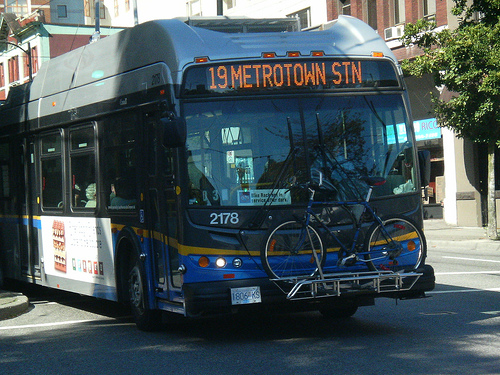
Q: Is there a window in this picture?
A: Yes, there is a window.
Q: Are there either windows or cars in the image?
A: Yes, there is a window.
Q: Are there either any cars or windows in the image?
A: Yes, there is a window.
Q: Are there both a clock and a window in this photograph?
A: No, there is a window but no clocks.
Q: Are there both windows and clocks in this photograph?
A: No, there is a window but no clocks.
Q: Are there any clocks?
A: No, there are no clocks.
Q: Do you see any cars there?
A: No, there are no cars.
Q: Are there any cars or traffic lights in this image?
A: No, there are no cars or traffic lights.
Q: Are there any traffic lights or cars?
A: No, there are no cars or traffic lights.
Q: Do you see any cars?
A: No, there are no cars.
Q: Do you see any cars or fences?
A: No, there are no cars or fences.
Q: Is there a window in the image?
A: Yes, there is a window.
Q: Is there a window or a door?
A: Yes, there is a window.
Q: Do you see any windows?
A: Yes, there is a window.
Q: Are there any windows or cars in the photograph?
A: Yes, there is a window.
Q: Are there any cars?
A: No, there are no cars.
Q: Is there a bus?
A: Yes, there is a bus.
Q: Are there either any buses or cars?
A: Yes, there is a bus.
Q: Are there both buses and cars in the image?
A: No, there is a bus but no cars.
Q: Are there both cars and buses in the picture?
A: No, there is a bus but no cars.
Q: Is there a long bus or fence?
A: Yes, there is a long bus.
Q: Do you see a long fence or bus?
A: Yes, there is a long bus.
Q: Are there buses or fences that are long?
A: Yes, the bus is long.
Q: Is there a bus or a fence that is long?
A: Yes, the bus is long.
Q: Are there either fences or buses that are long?
A: Yes, the bus is long.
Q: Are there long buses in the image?
A: Yes, there is a long bus.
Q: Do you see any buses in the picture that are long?
A: Yes, there is a bus that is long.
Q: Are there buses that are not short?
A: Yes, there is a long bus.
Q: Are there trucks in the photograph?
A: No, there are no trucks.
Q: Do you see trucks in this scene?
A: No, there are no trucks.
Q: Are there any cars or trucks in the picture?
A: No, there are no trucks or cars.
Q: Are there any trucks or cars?
A: No, there are no trucks or cars.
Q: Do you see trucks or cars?
A: No, there are no trucks or cars.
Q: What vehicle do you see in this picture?
A: The vehicle is a bus.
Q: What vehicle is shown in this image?
A: The vehicle is a bus.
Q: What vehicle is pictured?
A: The vehicle is a bus.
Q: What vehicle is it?
A: The vehicle is a bus.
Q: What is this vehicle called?
A: This is a bus.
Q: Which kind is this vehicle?
A: This is a bus.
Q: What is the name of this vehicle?
A: This is a bus.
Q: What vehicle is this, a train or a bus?
A: This is a bus.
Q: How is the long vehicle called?
A: The vehicle is a bus.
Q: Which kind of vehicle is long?
A: The vehicle is a bus.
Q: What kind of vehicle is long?
A: The vehicle is a bus.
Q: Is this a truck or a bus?
A: This is a bus.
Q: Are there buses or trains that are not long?
A: No, there is a bus but it is long.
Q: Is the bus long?
A: Yes, the bus is long.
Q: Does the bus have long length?
A: Yes, the bus is long.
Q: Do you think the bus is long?
A: Yes, the bus is long.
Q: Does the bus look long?
A: Yes, the bus is long.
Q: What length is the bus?
A: The bus is long.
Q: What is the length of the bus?
A: The bus is long.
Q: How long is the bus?
A: The bus is long.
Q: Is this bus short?
A: No, the bus is long.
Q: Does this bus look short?
A: No, the bus is long.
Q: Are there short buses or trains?
A: No, there is a bus but it is long.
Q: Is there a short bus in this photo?
A: No, there is a bus but it is long.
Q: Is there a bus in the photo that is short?
A: No, there is a bus but it is long.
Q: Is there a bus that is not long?
A: No, there is a bus but it is long.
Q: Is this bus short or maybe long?
A: The bus is long.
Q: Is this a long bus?
A: Yes, this is a long bus.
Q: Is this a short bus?
A: No, this is a long bus.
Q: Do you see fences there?
A: No, there are no fences.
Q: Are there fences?
A: No, there are no fences.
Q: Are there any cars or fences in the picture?
A: No, there are no fences or cars.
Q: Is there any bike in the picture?
A: Yes, there is a bike.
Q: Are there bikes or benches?
A: Yes, there is a bike.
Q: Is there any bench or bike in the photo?
A: Yes, there is a bike.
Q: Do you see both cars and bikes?
A: No, there is a bike but no cars.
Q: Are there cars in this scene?
A: No, there are no cars.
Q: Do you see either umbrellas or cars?
A: No, there are no cars or umbrellas.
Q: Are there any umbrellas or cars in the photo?
A: No, there are no cars or umbrellas.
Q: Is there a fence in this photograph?
A: No, there are no fences.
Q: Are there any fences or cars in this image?
A: No, there are no fences or cars.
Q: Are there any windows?
A: Yes, there is a window.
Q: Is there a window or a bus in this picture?
A: Yes, there is a window.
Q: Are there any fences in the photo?
A: No, there are no fences.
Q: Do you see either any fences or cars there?
A: No, there are no fences or cars.